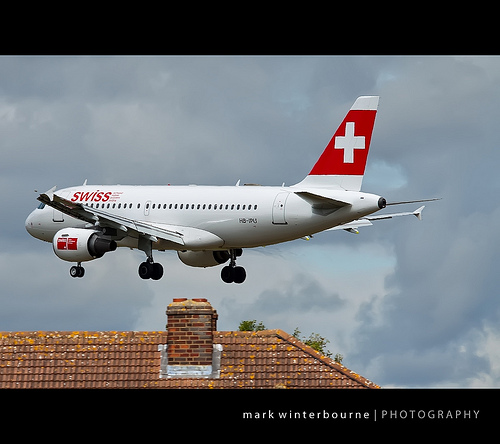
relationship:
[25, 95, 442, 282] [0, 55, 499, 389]
plane flying in air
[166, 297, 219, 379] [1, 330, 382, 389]
chimney sitting on roof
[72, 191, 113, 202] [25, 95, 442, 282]
writing on side of plane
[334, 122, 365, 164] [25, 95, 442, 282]
cross on side of plane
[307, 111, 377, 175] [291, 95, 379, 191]
part of tail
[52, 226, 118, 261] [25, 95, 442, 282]
engine of plane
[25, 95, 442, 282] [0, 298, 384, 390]
plane flying over house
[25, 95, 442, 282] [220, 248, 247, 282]
plane with gear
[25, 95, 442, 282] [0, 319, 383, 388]
plane flying over neighborhood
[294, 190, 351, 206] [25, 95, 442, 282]
wing of plane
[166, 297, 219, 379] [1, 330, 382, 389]
chimney on side of roof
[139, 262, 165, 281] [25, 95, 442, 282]
wheels on both sides of plane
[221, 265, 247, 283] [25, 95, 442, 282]
wheels on both sides of plane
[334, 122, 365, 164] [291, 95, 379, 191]
cross painted on tail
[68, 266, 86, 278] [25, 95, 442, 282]
wheels on plane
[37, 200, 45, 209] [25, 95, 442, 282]
windshield of plane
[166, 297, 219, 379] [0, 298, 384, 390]
chimney sitting on house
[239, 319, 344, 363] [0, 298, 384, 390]
tree behind house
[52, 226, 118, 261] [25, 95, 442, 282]
engine attached on plane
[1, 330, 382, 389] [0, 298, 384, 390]
roof of house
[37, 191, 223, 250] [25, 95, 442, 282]
wing of plane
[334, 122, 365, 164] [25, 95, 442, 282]
cross on tail of plane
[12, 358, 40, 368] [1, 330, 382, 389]
tile covering on roof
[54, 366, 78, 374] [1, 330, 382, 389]
tile covering on roof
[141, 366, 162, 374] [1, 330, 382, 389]
tile covering on roof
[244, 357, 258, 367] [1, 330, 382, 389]
tile covering on roof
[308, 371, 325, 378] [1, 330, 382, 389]
tile covering on roof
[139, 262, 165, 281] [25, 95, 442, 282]
wheels of plane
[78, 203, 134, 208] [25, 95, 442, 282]
windows on side of plane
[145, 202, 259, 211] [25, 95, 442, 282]
windows on side of plane